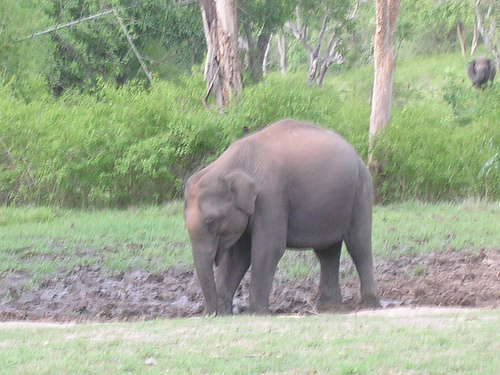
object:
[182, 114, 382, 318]
elephant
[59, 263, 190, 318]
dirt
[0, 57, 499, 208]
bushes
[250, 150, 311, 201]
skin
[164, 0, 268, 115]
tree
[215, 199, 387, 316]
legs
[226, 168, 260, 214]
ear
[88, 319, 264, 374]
grass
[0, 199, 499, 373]
ground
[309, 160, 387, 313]
back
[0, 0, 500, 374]
background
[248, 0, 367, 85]
branches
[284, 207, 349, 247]
stomach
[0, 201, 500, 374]
field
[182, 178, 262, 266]
head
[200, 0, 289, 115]
trunk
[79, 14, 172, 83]
leaves